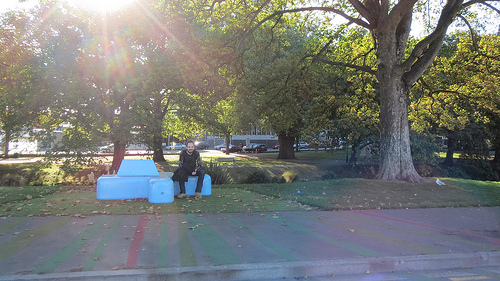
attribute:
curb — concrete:
[9, 249, 499, 279]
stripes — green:
[0, 208, 500, 279]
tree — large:
[330, 14, 462, 169]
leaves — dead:
[284, 173, 454, 223]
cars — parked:
[195, 133, 350, 153]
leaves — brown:
[2, 185, 97, 217]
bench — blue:
[97, 152, 214, 211]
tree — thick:
[231, 2, 499, 175]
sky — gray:
[289, 11, 499, 68]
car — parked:
[227, 143, 273, 168]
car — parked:
[195, 139, 208, 149]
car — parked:
[221, 142, 241, 153]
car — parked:
[249, 142, 268, 152]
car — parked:
[97, 140, 114, 151]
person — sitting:
[171, 141, 216, 208]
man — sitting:
[150, 112, 240, 209]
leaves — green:
[0, 1, 497, 143]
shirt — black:
[167, 129, 217, 178]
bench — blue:
[95, 161, 172, 207]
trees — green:
[1, 0, 498, 181]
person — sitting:
[168, 132, 208, 208]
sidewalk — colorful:
[2, 204, 498, 278]